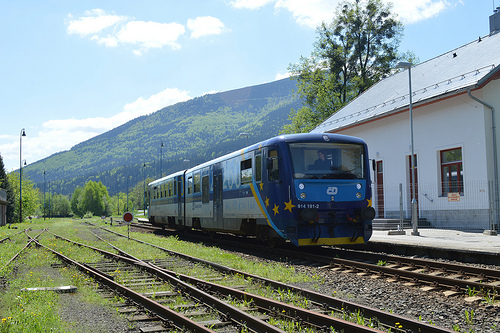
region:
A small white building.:
[330, 34, 496, 238]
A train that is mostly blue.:
[133, 123, 383, 260]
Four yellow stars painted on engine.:
[253, 180, 298, 216]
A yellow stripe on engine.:
[240, 176, 307, 245]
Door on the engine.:
[201, 164, 233, 231]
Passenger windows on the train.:
[148, 165, 250, 199]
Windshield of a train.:
[288, 139, 370, 182]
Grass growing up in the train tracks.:
[5, 203, 486, 330]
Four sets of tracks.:
[6, 222, 496, 329]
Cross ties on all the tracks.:
[6, 238, 491, 329]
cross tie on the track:
[398, 274, 415, 286]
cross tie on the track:
[459, 294, 479, 309]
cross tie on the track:
[124, 311, 149, 321]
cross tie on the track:
[106, 300, 132, 310]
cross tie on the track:
[139, 320, 167, 332]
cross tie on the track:
[96, 288, 116, 297]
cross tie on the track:
[338, 267, 351, 276]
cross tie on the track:
[380, 276, 393, 285]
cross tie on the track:
[462, 292, 482, 302]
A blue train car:
[172, 124, 366, 254]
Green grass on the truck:
[248, 253, 316, 285]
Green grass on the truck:
[161, 227, 216, 258]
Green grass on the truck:
[7, 293, 64, 328]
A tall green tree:
[302, 17, 392, 125]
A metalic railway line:
[365, 236, 452, 293]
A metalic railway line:
[315, 279, 436, 331]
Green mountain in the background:
[6, 70, 366, 192]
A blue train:
[143, 132, 374, 247]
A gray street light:
[396, 58, 420, 235]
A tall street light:
[19, 127, 26, 224]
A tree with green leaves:
[283, 0, 417, 130]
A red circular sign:
[122, 210, 134, 239]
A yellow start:
[282, 199, 294, 211]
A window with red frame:
[440, 145, 464, 191]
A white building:
[310, 33, 497, 230]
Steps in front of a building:
[373, 216, 430, 228]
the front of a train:
[192, 105, 424, 257]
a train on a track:
[222, 105, 462, 250]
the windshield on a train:
[265, 123, 420, 193]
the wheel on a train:
[222, 216, 326, 252]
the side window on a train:
[172, 124, 313, 219]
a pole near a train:
[373, 43, 450, 245]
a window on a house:
[401, 135, 491, 210]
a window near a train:
[427, 135, 489, 225]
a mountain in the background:
[72, 45, 268, 179]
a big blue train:
[205, 144, 367, 248]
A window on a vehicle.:
[241, 158, 256, 185]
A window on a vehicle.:
[202, 174, 214, 201]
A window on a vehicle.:
[190, 173, 203, 193]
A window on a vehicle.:
[187, 178, 197, 191]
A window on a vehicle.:
[166, 181, 172, 196]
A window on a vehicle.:
[161, 182, 168, 195]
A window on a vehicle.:
[158, 184, 164, 199]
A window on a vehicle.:
[156, 184, 164, 194]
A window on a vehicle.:
[151, 185, 161, 202]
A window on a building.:
[433, 150, 464, 202]